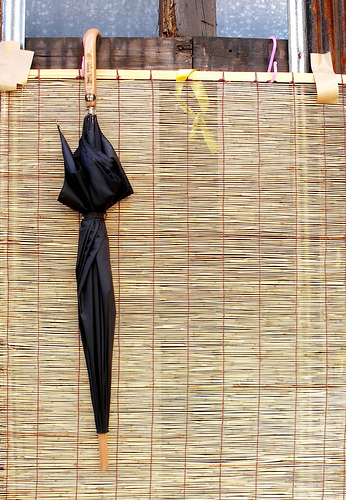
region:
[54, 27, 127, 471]
black umbrella with bamboo handle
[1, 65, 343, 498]
bamboo shade with red twine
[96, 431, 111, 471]
bamboo umbrella tip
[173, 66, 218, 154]
yellow ribbon tied around shade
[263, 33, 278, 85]
pink plastic hook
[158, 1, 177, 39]
rotted piece of wood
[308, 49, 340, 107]
strip of packing tape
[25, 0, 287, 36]
white frosted glass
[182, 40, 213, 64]
nails holding up wood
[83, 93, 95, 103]
black sticker on umbrella handle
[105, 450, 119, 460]
tip of an umbrella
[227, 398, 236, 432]
part of a window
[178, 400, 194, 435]
edge of a window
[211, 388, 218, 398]
part of a window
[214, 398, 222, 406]
side of a window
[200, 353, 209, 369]
edge of a pane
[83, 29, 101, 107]
A brown handle of an umbrella.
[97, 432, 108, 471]
A brown tip on an umbrella.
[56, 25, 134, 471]
A brown and black umbrella.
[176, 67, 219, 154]
A yellow ribbon in front of and behind a brown blind.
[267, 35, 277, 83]
A pink S hook.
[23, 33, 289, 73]
A long brown board with a umbrella hook and pink hook attached to it.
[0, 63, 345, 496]
A long brown blind with red lines down it.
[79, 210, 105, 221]
A black strap going around a black umbrella that keeps it closed.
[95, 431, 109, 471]
Light brown tip of a umbrella.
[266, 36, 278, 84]
A pink hook.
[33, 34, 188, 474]
Black umbrella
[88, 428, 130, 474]
Umbrella has a tip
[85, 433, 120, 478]
tips is light brown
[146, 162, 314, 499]
Basket is made of wood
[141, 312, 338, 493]
These are individual stands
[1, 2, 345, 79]
A window in the background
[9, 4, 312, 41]
The window is blue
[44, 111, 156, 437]
This is made of leather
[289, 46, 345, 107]
A handel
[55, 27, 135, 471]
a black and wood grain umbrella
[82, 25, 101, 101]
wood handle for umbrella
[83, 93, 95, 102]
a small black oval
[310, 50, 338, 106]
brown piece of tape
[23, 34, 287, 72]
old rotten wood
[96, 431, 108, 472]
tip of an umbrella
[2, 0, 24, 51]
metal siding on a window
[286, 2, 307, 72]
metal siding on a window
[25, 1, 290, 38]
a dirty window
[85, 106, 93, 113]
metal rod inside umbrella